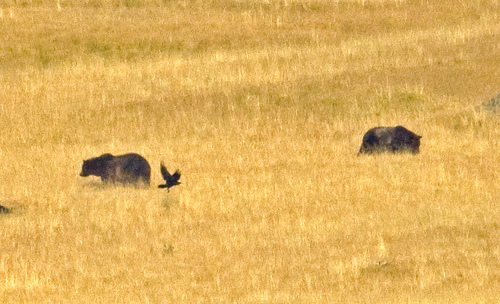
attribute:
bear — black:
[357, 125, 421, 155]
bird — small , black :
[143, 160, 191, 205]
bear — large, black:
[79, 147, 154, 182]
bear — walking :
[355, 124, 424, 158]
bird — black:
[155, 156, 184, 194]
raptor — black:
[151, 159, 188, 198]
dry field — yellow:
[244, 117, 289, 205]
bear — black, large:
[347, 108, 427, 169]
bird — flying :
[152, 165, 201, 195]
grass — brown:
[233, 167, 408, 281]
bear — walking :
[76, 150, 153, 187]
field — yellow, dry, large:
[1, 0, 498, 302]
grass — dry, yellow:
[14, 5, 496, 302]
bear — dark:
[356, 124, 421, 161]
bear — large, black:
[75, 151, 147, 187]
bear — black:
[351, 119, 433, 166]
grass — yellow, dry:
[211, 190, 361, 256]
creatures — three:
[36, 96, 442, 219]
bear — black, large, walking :
[80, 152, 150, 184]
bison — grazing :
[77, 153, 152, 186]